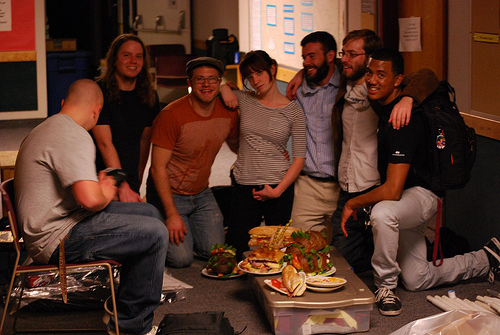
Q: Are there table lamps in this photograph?
A: No, there are no table lamps.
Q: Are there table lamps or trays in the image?
A: No, there are no table lamps or trays.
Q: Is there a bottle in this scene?
A: No, there are no bottles.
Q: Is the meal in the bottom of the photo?
A: Yes, the meal is in the bottom of the image.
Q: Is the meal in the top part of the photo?
A: No, the meal is in the bottom of the image.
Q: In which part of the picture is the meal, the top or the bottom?
A: The meal is in the bottom of the image.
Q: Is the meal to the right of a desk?
A: No, the meal is to the right of the chair.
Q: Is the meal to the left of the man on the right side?
A: Yes, the meal is to the left of the man.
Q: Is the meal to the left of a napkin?
A: No, the meal is to the left of the man.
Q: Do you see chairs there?
A: Yes, there is a chair.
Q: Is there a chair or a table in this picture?
A: Yes, there is a chair.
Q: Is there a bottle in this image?
A: No, there are no bottles.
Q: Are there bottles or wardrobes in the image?
A: No, there are no bottles or wardrobes.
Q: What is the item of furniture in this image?
A: The piece of furniture is a chair.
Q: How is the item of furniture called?
A: The piece of furniture is a chair.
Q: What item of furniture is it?
A: The piece of furniture is a chair.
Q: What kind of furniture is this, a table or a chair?
A: This is a chair.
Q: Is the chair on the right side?
A: No, the chair is on the left of the image.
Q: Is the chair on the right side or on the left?
A: The chair is on the left of the image.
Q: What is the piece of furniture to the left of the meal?
A: The piece of furniture is a chair.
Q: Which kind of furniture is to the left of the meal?
A: The piece of furniture is a chair.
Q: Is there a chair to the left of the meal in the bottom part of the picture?
A: Yes, there is a chair to the left of the meal.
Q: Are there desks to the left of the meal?
A: No, there is a chair to the left of the meal.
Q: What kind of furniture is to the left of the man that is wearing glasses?
A: The piece of furniture is a chair.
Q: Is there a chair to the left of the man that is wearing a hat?
A: Yes, there is a chair to the left of the man.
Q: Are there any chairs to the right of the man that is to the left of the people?
A: No, the chair is to the left of the man.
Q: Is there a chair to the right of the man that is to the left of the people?
A: No, the chair is to the left of the man.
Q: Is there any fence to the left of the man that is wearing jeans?
A: No, there is a chair to the left of the man.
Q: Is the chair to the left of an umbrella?
A: No, the chair is to the left of a man.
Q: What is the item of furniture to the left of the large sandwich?
A: The piece of furniture is a chair.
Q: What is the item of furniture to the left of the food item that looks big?
A: The piece of furniture is a chair.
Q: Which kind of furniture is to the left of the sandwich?
A: The piece of furniture is a chair.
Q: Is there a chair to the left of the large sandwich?
A: Yes, there is a chair to the left of the sandwich.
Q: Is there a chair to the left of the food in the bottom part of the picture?
A: Yes, there is a chair to the left of the sandwich.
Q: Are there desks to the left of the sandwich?
A: No, there is a chair to the left of the sandwich.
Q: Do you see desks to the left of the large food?
A: No, there is a chair to the left of the sandwich.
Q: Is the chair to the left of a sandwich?
A: Yes, the chair is to the left of a sandwich.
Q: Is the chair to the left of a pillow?
A: No, the chair is to the left of a sandwich.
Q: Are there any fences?
A: No, there are no fences.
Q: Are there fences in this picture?
A: No, there are no fences.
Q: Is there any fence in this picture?
A: No, there are no fences.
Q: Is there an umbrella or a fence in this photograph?
A: No, there are no fences or umbrellas.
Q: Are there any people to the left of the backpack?
A: Yes, there are people to the left of the backpack.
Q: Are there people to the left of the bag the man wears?
A: Yes, there are people to the left of the backpack.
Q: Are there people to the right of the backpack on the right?
A: No, the people are to the left of the backpack.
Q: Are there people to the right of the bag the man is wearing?
A: No, the people are to the left of the backpack.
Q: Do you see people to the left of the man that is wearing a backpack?
A: Yes, there are people to the left of the man.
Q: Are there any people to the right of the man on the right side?
A: No, the people are to the left of the man.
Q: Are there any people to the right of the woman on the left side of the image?
A: Yes, there are people to the right of the woman.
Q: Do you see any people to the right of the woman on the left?
A: Yes, there are people to the right of the woman.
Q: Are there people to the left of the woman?
A: No, the people are to the right of the woman.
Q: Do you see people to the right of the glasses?
A: Yes, there are people to the right of the glasses.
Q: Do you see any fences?
A: No, there are no fences.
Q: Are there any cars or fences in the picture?
A: No, there are no fences or cars.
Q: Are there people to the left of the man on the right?
A: Yes, there are people to the left of the man.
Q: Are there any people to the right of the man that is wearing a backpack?
A: No, the people are to the left of the man.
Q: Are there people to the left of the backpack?
A: Yes, there are people to the left of the backpack.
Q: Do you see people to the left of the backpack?
A: Yes, there are people to the left of the backpack.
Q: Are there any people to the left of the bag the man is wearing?
A: Yes, there are people to the left of the backpack.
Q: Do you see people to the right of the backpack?
A: No, the people are to the left of the backpack.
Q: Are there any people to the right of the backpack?
A: No, the people are to the left of the backpack.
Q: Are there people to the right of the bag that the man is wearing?
A: No, the people are to the left of the backpack.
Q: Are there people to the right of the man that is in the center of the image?
A: Yes, there are people to the right of the man.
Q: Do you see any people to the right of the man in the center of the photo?
A: Yes, there are people to the right of the man.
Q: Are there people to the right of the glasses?
A: Yes, there are people to the right of the glasses.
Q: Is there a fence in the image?
A: No, there are no fences.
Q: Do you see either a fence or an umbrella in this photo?
A: No, there are no fences or umbrellas.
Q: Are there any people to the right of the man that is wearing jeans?
A: Yes, there are people to the right of the man.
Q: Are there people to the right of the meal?
A: Yes, there are people to the right of the meal.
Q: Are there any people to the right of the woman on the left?
A: Yes, there are people to the right of the woman.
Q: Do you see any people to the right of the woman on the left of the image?
A: Yes, there are people to the right of the woman.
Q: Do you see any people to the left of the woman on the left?
A: No, the people are to the right of the woman.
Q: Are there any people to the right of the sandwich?
A: Yes, there are people to the right of the sandwich.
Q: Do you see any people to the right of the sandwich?
A: Yes, there are people to the right of the sandwich.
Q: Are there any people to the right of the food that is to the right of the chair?
A: Yes, there are people to the right of the sandwich.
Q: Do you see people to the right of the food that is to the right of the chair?
A: Yes, there are people to the right of the sandwich.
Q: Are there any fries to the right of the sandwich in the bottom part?
A: No, there are people to the right of the sandwich.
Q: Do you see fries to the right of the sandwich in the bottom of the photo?
A: No, there are people to the right of the sandwich.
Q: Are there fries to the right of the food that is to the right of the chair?
A: No, there are people to the right of the sandwich.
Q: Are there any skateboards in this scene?
A: No, there are no skateboards.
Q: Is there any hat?
A: Yes, there is a hat.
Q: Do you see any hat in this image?
A: Yes, there is a hat.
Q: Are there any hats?
A: Yes, there is a hat.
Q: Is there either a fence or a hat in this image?
A: Yes, there is a hat.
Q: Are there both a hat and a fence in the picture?
A: No, there is a hat but no fences.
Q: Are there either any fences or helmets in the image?
A: No, there are no fences or helmets.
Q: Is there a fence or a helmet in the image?
A: No, there are no fences or helmets.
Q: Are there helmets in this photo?
A: No, there are no helmets.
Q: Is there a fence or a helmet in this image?
A: No, there are no helmets or fences.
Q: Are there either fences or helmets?
A: No, there are no helmets or fences.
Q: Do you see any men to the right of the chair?
A: Yes, there is a man to the right of the chair.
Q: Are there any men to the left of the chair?
A: No, the man is to the right of the chair.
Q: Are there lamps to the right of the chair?
A: No, there is a man to the right of the chair.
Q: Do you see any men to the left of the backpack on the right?
A: Yes, there is a man to the left of the backpack.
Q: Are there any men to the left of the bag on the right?
A: Yes, there is a man to the left of the backpack.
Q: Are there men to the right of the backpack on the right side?
A: No, the man is to the left of the backpack.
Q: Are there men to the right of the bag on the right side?
A: No, the man is to the left of the backpack.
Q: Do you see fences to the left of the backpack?
A: No, there is a man to the left of the backpack.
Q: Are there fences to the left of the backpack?
A: No, there is a man to the left of the backpack.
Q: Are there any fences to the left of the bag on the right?
A: No, there is a man to the left of the backpack.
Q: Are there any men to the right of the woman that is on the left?
A: Yes, there is a man to the right of the woman.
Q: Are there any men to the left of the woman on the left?
A: No, the man is to the right of the woman.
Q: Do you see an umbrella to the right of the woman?
A: No, there is a man to the right of the woman.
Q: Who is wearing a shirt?
A: The man is wearing a shirt.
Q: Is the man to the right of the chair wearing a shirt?
A: Yes, the man is wearing a shirt.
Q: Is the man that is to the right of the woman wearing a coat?
A: No, the man is wearing a shirt.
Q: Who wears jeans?
A: The man wears jeans.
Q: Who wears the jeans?
A: The man wears jeans.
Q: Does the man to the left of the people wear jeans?
A: Yes, the man wears jeans.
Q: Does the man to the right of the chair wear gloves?
A: No, the man wears jeans.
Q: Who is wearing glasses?
A: The man is wearing glasses.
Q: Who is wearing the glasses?
A: The man is wearing glasses.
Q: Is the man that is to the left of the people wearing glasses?
A: Yes, the man is wearing glasses.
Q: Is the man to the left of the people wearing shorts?
A: No, the man is wearing glasses.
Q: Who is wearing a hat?
A: The man is wearing a hat.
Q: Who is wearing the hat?
A: The man is wearing a hat.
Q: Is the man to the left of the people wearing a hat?
A: Yes, the man is wearing a hat.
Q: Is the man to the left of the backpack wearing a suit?
A: No, the man is wearing a hat.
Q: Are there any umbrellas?
A: No, there are no umbrellas.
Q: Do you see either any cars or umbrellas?
A: No, there are no umbrellas or cars.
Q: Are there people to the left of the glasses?
A: Yes, there are people to the left of the glasses.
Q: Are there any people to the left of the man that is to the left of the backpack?
A: Yes, there are people to the left of the man.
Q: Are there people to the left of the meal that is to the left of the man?
A: Yes, there are people to the left of the meal.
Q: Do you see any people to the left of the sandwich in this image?
A: Yes, there are people to the left of the sandwich.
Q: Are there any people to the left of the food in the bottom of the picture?
A: Yes, there are people to the left of the sandwich.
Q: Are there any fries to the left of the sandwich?
A: No, there are people to the left of the sandwich.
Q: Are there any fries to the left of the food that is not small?
A: No, there are people to the left of the sandwich.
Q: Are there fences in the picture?
A: No, there are no fences.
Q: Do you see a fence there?
A: No, there are no fences.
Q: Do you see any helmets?
A: No, there are no helmets.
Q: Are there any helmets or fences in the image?
A: No, there are no helmets or fences.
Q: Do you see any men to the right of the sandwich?
A: Yes, there is a man to the right of the sandwich.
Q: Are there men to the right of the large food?
A: Yes, there is a man to the right of the sandwich.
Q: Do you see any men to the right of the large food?
A: Yes, there is a man to the right of the sandwich.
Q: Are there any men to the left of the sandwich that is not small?
A: No, the man is to the right of the sandwich.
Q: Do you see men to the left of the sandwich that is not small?
A: No, the man is to the right of the sandwich.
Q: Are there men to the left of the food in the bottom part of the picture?
A: No, the man is to the right of the sandwich.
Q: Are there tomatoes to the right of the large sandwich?
A: No, there is a man to the right of the sandwich.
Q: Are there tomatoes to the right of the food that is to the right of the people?
A: No, there is a man to the right of the sandwich.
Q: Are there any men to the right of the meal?
A: Yes, there is a man to the right of the meal.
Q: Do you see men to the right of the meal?
A: Yes, there is a man to the right of the meal.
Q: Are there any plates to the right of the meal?
A: No, there is a man to the right of the meal.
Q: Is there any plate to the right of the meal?
A: No, there is a man to the right of the meal.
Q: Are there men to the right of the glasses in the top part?
A: Yes, there is a man to the right of the glasses.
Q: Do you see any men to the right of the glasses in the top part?
A: Yes, there is a man to the right of the glasses.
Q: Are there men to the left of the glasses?
A: No, the man is to the right of the glasses.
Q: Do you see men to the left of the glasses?
A: No, the man is to the right of the glasses.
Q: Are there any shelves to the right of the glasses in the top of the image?
A: No, there is a man to the right of the glasses.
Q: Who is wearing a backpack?
A: The man is wearing a backpack.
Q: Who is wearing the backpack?
A: The man is wearing a backpack.